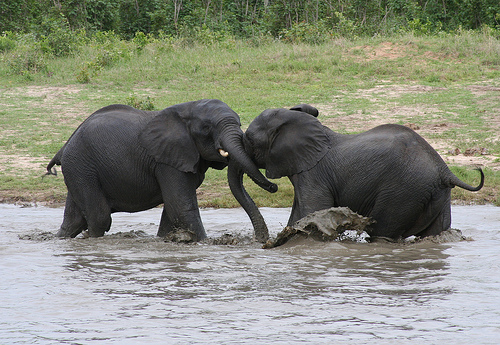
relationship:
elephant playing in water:
[26, 87, 283, 274] [0, 197, 499, 343]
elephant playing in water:
[219, 86, 493, 277] [0, 197, 499, 343]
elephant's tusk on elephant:
[218, 148, 228, 157] [43, 98, 280, 243]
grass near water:
[286, 67, 355, 97] [10, 207, 471, 324]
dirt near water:
[373, 71, 425, 93] [10, 207, 471, 324]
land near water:
[24, 31, 484, 158] [10, 207, 471, 324]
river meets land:
[7, 205, 498, 335] [14, 17, 486, 113]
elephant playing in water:
[226, 104, 485, 245] [82, 255, 445, 323]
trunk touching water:
[223, 151, 273, 242] [0, 197, 499, 343]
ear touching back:
[249, 116, 346, 183] [101, 109, 152, 136]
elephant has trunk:
[43, 98, 280, 243] [224, 132, 286, 195]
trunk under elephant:
[224, 132, 286, 195] [226, 104, 485, 245]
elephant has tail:
[226, 104, 485, 245] [450, 167, 485, 193]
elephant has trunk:
[43, 98, 280, 243] [223, 131, 280, 195]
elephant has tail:
[226, 104, 485, 245] [445, 163, 485, 193]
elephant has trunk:
[43, 98, 280, 243] [217, 118, 278, 194]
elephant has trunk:
[226, 104, 485, 245] [227, 135, 271, 245]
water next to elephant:
[24, 240, 425, 340] [52, 90, 236, 214]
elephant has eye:
[43, 98, 280, 243] [197, 118, 212, 140]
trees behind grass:
[124, 1, 280, 58] [0, 31, 499, 201]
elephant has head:
[43, 98, 280, 243] [132, 97, 283, 196]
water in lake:
[393, 227, 461, 275] [8, 189, 498, 339]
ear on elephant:
[136, 103, 199, 174] [43, 98, 280, 243]